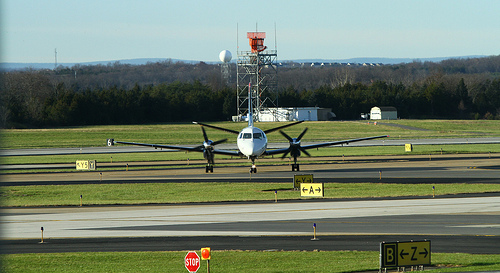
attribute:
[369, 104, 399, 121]
hangar — small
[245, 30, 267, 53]
building — red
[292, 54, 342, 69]
buildings — distant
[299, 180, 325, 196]
sign — yellow, black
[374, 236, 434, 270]
sign — yellow, black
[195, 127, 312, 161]
twin propeller — white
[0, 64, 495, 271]
airport — small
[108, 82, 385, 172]
plane — parked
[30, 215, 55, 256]
light — beacon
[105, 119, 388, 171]
plane — sitting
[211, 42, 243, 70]
tower — white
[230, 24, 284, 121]
communication tower — steel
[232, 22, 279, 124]
tower — radio tower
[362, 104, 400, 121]
barn — white